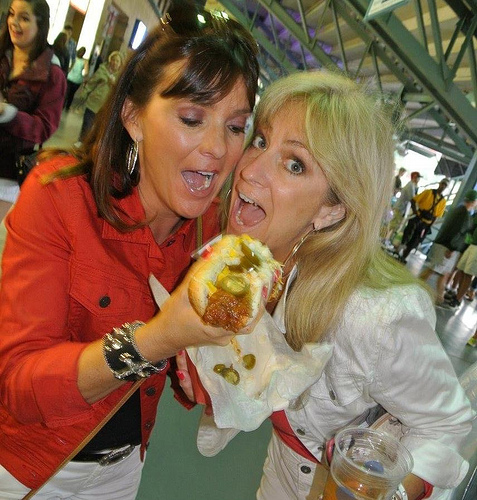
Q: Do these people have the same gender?
A: No, they are both male and female.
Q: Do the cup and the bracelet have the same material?
A: No, the cup is made of plastic and the bracelet is made of metal.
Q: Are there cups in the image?
A: Yes, there is a cup.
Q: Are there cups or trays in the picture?
A: Yes, there is a cup.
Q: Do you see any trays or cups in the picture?
A: Yes, there is a cup.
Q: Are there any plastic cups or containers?
A: Yes, there is a plastic cup.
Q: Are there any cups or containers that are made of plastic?
A: Yes, the cup is made of plastic.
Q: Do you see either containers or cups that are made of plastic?
A: Yes, the cup is made of plastic.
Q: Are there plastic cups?
A: Yes, there is a cup that is made of plastic.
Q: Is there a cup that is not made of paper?
A: Yes, there is a cup that is made of plastic.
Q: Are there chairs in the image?
A: No, there are no chairs.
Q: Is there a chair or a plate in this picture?
A: No, there are no chairs or plates.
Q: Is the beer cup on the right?
A: Yes, the cup is on the right of the image.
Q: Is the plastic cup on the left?
A: No, the cup is on the right of the image.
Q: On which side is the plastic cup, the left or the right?
A: The cup is on the right of the image.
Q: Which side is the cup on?
A: The cup is on the right of the image.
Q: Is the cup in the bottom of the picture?
A: Yes, the cup is in the bottom of the image.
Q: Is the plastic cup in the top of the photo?
A: No, the cup is in the bottom of the image.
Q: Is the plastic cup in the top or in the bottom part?
A: The cup is in the bottom of the image.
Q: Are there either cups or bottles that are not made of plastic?
A: No, there is a cup but it is made of plastic.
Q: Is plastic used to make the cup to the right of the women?
A: Yes, the cup is made of plastic.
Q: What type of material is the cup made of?
A: The cup is made of plastic.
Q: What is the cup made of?
A: The cup is made of plastic.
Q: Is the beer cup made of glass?
A: No, the cup is made of plastic.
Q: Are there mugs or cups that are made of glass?
A: No, there is a cup but it is made of plastic.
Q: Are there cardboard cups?
A: No, there is a cup but it is made of plastic.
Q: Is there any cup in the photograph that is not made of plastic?
A: No, there is a cup but it is made of plastic.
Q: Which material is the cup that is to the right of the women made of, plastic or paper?
A: The cup is made of plastic.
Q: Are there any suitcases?
A: No, there are no suitcases.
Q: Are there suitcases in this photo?
A: No, there are no suitcases.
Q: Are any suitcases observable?
A: No, there are no suitcases.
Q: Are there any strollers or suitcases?
A: No, there are no suitcases or strollers.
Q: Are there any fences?
A: No, there are no fences.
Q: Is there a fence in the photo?
A: No, there are no fences.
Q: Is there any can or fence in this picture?
A: No, there are no fences or cans.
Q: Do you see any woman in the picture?
A: Yes, there is a woman.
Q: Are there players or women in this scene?
A: Yes, there is a woman.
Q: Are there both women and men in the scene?
A: Yes, there are both a woman and a man.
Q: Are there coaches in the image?
A: No, there are no coaches.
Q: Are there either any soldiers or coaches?
A: No, there are no coaches or soldiers.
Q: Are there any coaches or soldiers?
A: No, there are no coaches or soldiers.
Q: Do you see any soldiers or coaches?
A: No, there are no coaches or soldiers.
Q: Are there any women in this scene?
A: Yes, there are women.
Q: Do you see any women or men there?
A: Yes, there are women.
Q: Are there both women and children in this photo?
A: No, there are women but no children.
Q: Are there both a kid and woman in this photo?
A: No, there are women but no children.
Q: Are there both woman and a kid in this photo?
A: No, there are women but no children.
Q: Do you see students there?
A: No, there are no students.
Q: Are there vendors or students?
A: No, there are no students or vendors.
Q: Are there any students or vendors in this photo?
A: No, there are no students or vendors.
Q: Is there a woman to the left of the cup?
A: Yes, there are women to the left of the cup.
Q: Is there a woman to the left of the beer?
A: Yes, there are women to the left of the beer.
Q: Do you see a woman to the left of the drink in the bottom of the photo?
A: Yes, there are women to the left of the beer.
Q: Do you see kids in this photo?
A: No, there are no kids.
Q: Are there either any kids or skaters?
A: No, there are no kids or skaters.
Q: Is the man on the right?
A: Yes, the man is on the right of the image.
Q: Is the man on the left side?
A: No, the man is on the right of the image.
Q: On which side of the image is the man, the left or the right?
A: The man is on the right of the image.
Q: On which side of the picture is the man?
A: The man is on the right of the image.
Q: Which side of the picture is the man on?
A: The man is on the right of the image.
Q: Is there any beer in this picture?
A: Yes, there is beer.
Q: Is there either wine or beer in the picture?
A: Yes, there is beer.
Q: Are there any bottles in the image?
A: No, there are no bottles.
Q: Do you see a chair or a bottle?
A: No, there are no bottles or chairs.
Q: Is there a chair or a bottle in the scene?
A: No, there are no bottles or chairs.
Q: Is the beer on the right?
A: Yes, the beer is on the right of the image.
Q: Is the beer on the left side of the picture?
A: No, the beer is on the right of the image.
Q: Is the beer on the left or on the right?
A: The beer is on the right of the image.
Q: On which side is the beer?
A: The beer is on the right of the image.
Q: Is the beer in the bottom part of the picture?
A: Yes, the beer is in the bottom of the image.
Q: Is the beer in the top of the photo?
A: No, the beer is in the bottom of the image.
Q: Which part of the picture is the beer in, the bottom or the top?
A: The beer is in the bottom of the image.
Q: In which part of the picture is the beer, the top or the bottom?
A: The beer is in the bottom of the image.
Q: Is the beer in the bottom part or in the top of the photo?
A: The beer is in the bottom of the image.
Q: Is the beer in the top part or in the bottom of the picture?
A: The beer is in the bottom of the image.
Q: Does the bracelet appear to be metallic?
A: Yes, the bracelet is metallic.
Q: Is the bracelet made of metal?
A: Yes, the bracelet is made of metal.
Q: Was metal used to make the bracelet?
A: Yes, the bracelet is made of metal.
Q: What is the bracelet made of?
A: The bracelet is made of metal.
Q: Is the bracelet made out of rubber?
A: No, the bracelet is made of metal.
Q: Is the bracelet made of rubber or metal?
A: The bracelet is made of metal.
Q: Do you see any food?
A: Yes, there is food.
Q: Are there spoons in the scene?
A: No, there are no spoons.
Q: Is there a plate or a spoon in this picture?
A: No, there are no spoons or plates.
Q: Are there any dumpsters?
A: No, there are no dumpsters.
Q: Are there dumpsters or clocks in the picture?
A: No, there are no dumpsters or clocks.